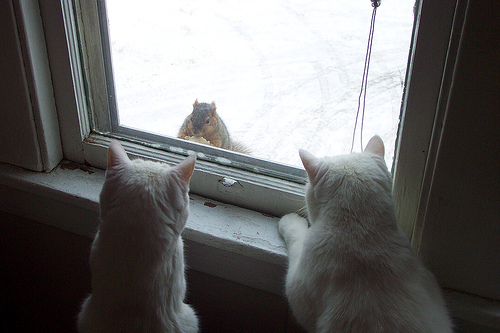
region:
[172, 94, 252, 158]
squirrel standing outside of house window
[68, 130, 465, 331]
two cats looking out of house window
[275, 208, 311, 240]
one white cat paw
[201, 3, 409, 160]
tracks in white snow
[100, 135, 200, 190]
two cat ears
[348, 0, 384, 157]
blinds drawstring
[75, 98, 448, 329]
2 cats at a window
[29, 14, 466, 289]
this is a window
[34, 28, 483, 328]
cats are facing the window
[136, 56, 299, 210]
this is a squirrel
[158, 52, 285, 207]
the squirrel is at the window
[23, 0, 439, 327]
the window seal is white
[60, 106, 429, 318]
the cats are white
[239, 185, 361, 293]
cat paw is white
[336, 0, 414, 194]
chord hanging in window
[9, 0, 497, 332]
a scene inside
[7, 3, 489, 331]
a scene during the day time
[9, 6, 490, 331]
a scene in a house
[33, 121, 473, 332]
two cats looking outside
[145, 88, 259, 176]
a rodent looking into the window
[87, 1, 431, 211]
white snow on the ground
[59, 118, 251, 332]
a white cat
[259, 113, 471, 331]
a fat cat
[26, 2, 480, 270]
a white window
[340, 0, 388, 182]
a white blind string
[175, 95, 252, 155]
black and brown squirrel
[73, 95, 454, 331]
two cats watching a squirrel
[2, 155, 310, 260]
white window ledge with chipping paint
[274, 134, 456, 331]
white cat with paw on window sill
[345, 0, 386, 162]
two hanging strings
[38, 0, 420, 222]
window with a white wood trim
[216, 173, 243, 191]
small metal handle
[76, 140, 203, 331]
white cat with pink ears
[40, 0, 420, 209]
squirrel outside of a window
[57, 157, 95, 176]
area of chipped paint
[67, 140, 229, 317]
This is a cat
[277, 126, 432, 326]
This is a cat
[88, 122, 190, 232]
This is a cat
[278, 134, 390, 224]
This is a cat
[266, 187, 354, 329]
This is a cat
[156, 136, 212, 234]
This is a cat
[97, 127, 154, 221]
This is a cat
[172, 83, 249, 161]
This is a cat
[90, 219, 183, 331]
This is a cat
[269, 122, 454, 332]
this is a cat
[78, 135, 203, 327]
this is a cat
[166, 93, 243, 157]
this is a squiarell